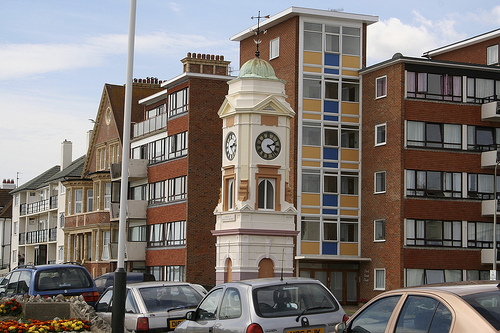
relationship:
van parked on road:
[0, 263, 101, 311] [1, 297, 500, 332]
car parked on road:
[170, 275, 351, 332] [1, 297, 500, 332]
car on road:
[90, 279, 208, 332] [1, 297, 500, 332]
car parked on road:
[332, 279, 499, 332] [1, 297, 500, 332]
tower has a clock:
[211, 10, 300, 284] [254, 129, 282, 161]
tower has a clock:
[211, 10, 300, 284] [223, 131, 238, 161]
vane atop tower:
[248, 8, 271, 58] [211, 10, 300, 284]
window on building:
[370, 74, 390, 100] [109, 7, 500, 313]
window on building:
[372, 121, 390, 149] [109, 7, 500, 313]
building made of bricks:
[109, 7, 500, 313] [190, 83, 213, 280]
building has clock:
[109, 7, 500, 313] [254, 129, 282, 161]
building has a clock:
[109, 7, 500, 313] [223, 131, 238, 161]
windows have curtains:
[404, 69, 464, 102] [407, 70, 429, 101]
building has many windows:
[109, 7, 500, 313] [299, 18, 389, 293]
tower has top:
[211, 10, 300, 284] [233, 56, 277, 79]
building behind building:
[10, 139, 86, 274] [109, 7, 500, 313]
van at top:
[0, 263, 101, 311] [233, 56, 277, 79]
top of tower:
[233, 56, 277, 79] [211, 10, 300, 284]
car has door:
[170, 275, 351, 332] [187, 283, 224, 332]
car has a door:
[170, 275, 351, 332] [273, 284, 305, 332]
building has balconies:
[109, 7, 500, 313] [110, 111, 169, 262]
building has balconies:
[109, 7, 500, 313] [477, 93, 499, 268]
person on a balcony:
[17, 252, 25, 266] [17, 260, 59, 280]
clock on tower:
[254, 129, 282, 161] [211, 10, 300, 284]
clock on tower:
[223, 131, 238, 161] [211, 10, 300, 284]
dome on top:
[238, 59, 280, 79] [233, 56, 277, 79]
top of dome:
[233, 56, 277, 79] [238, 59, 280, 79]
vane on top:
[248, 8, 271, 58] [233, 56, 277, 79]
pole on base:
[114, 0, 137, 270] [111, 266, 128, 332]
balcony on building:
[17, 260, 59, 280] [7, 154, 86, 272]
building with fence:
[7, 154, 86, 272] [17, 227, 57, 243]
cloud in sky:
[2, 31, 230, 79] [0, 1, 499, 188]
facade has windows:
[300, 50, 363, 258] [299, 18, 389, 293]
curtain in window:
[305, 23, 321, 52] [300, 21, 365, 56]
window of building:
[300, 21, 365, 56] [109, 7, 500, 313]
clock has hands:
[254, 129, 282, 161] [268, 139, 278, 153]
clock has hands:
[223, 131, 238, 161] [229, 141, 237, 154]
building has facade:
[109, 7, 500, 313] [300, 50, 363, 258]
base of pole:
[111, 266, 128, 332] [114, 0, 137, 270]